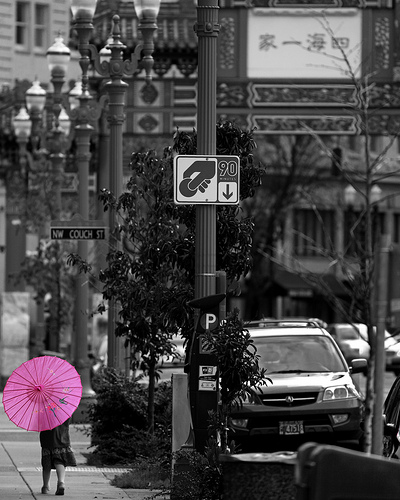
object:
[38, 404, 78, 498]
girl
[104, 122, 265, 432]
tree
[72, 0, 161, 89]
lamp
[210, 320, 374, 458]
car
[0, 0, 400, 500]
photo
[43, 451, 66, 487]
leg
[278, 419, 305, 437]
plate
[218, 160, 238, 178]
number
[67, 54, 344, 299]
background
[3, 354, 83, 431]
parasol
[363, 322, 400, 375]
vehicle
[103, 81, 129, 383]
pole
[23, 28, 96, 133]
light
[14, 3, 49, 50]
window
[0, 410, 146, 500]
sidewalk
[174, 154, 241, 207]
letter